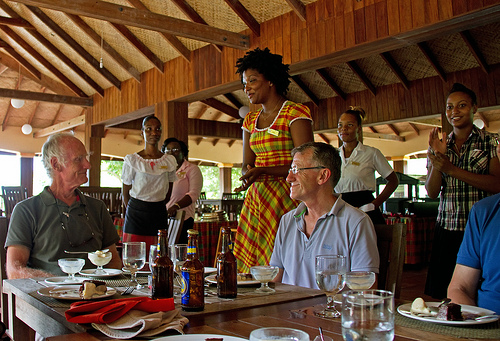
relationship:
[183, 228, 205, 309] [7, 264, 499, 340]
bottle on table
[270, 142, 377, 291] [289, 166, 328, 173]
man has on glasses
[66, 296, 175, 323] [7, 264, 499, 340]
napkin on table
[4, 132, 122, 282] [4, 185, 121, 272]
guy has on a shirt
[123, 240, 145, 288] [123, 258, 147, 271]
glass has water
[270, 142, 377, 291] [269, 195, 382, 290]
man has on a shirt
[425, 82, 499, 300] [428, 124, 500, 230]
wom has on a shirt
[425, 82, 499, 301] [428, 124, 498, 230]
woman dressed colorfully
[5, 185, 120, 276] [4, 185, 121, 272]
guy has on a shirt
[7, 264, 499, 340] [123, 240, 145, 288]
table has a glass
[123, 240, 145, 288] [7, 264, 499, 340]
glass on table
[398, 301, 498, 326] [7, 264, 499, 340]
plate on table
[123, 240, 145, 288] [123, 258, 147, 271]
glass filled with water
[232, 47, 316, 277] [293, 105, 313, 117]
waitress dressed in red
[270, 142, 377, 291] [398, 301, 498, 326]
man has a plate